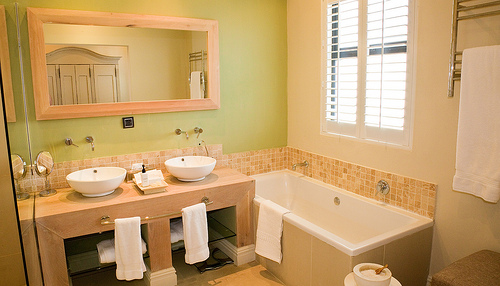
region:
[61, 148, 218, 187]
twin sinks in bathroom for two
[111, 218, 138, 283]
towel for drying hands and face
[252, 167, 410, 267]
bath tub for bathing in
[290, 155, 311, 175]
faucet for water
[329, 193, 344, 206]
drain so that tub doe not overflow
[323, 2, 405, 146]
window showing outside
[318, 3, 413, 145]
blinds on window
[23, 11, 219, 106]
mirror to show reflection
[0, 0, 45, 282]
body mirror for wall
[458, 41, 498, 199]
extra towel for drying body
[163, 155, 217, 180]
White sink on vanity.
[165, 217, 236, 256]
Glass shelf in vanity cabinet.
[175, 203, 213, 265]
White towel on rack.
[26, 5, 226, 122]
Mirror on the wall.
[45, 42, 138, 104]
Brown door reflected in the mirror.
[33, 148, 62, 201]
Hand mirror on counter.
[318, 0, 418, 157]
window on the wall.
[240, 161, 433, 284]
Bathtub against the wall.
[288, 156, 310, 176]
Silver colored faucet on the tub.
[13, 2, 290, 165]
Green wall in the background.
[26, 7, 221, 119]
mirror hanging on wall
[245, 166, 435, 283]
bathtub is deep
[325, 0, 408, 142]
white blinds in front of a window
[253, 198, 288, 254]
towel hanging on bathtub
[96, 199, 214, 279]
two towel hanging on towel rod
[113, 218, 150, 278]
towel to the left of towel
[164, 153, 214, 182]
white sink on top of counter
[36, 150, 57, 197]
mirror on top of counter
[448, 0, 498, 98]
metal towel rack on wall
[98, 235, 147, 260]
folded towel on top of shelf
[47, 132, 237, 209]
two white basin sinks on counter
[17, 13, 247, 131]
rectangle mirror on wall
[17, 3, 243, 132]
mirror has light brown trim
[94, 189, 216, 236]
towel rack on front of couter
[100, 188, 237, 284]
two tangles hanging on towel rack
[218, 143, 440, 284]
tub is white and square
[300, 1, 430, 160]
window above bathtub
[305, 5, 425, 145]
window had white blinds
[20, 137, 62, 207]
mirror on bathroom counter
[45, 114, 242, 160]
bathroom faucets mounted on wall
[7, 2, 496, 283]
bathroom in a home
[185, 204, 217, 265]
white towel on rack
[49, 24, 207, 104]
mirror on the wall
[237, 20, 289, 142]
green painted wall in bathroom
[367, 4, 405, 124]
blinds on the window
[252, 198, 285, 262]
white towel hanging from bathtub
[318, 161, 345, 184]
tile on the wall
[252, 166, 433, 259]
bathtub in the bathroom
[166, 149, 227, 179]
white sink on counter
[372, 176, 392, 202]
knob controlling the bath